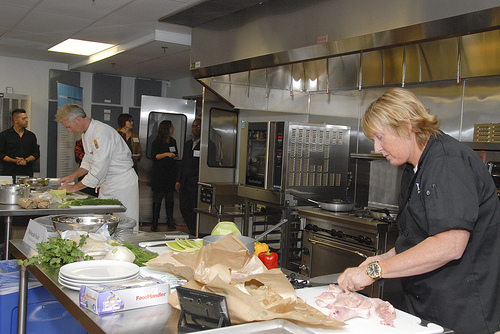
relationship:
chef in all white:
[59, 99, 150, 232] [80, 129, 125, 185]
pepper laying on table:
[258, 249, 278, 270] [12, 224, 427, 332]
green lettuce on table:
[31, 240, 95, 268] [31, 245, 419, 318]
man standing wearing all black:
[6, 107, 49, 174] [7, 130, 36, 162]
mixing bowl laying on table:
[207, 216, 248, 240] [34, 250, 425, 324]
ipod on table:
[164, 280, 235, 330] [7, 211, 469, 331]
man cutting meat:
[337, 87, 500, 334] [313, 280, 398, 328]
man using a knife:
[337, 87, 500, 334] [301, 264, 335, 289]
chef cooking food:
[58, 104, 140, 234] [19, 174, 52, 187]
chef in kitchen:
[58, 104, 140, 234] [0, 0, 499, 331]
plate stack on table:
[56, 254, 144, 298] [9, 228, 313, 331]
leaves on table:
[30, 230, 79, 277] [6, 234, 304, 332]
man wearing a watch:
[324, 86, 498, 331] [355, 254, 385, 283]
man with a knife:
[324, 86, 498, 331] [299, 268, 344, 291]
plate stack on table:
[58, 259, 141, 291] [6, 234, 304, 332]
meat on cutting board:
[312, 284, 397, 331] [286, 279, 438, 329]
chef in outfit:
[58, 104, 140, 234] [70, 115, 137, 216]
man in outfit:
[324, 86, 498, 331] [388, 132, 498, 319]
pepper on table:
[259, 248, 280, 278] [2, 224, 309, 327]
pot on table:
[1, 179, 37, 208] [2, 164, 131, 282]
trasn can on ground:
[4, 255, 76, 331] [6, 175, 335, 327]